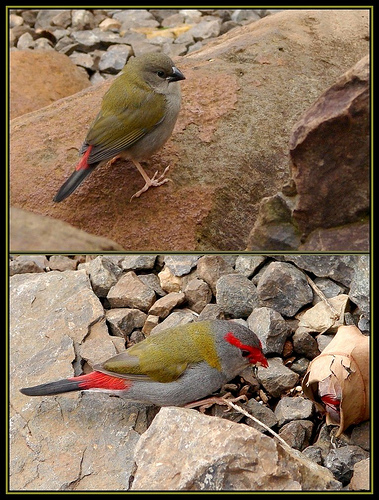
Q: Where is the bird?
A: On the rock.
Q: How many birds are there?
A: 2.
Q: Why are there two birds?
A: There are 2 photos.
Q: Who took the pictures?
A: The photographer.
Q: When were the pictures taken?
A: During the day.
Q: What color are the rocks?
A: Red and grey.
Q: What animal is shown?
A: Birds.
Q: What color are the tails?
A: Black and Red.